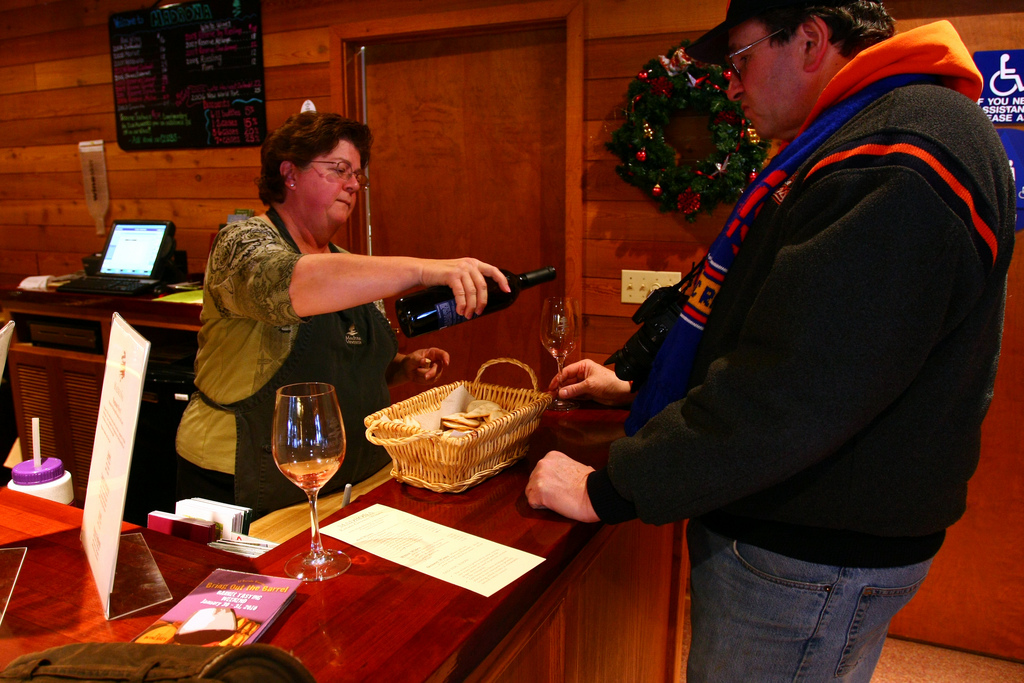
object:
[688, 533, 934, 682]
jeans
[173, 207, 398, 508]
apron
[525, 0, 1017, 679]
man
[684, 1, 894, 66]
hat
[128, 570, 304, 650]
menu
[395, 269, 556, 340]
bottle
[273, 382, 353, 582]
wine glass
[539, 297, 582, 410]
glass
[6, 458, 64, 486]
lid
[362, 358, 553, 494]
wick basket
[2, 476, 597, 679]
counter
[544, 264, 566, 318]
wine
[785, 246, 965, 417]
black jacket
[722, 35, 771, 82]
glasses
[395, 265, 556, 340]
wine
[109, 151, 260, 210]
wall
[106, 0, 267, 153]
menu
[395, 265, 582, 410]
wine/glass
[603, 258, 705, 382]
camera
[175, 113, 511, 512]
woman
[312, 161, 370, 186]
glasses